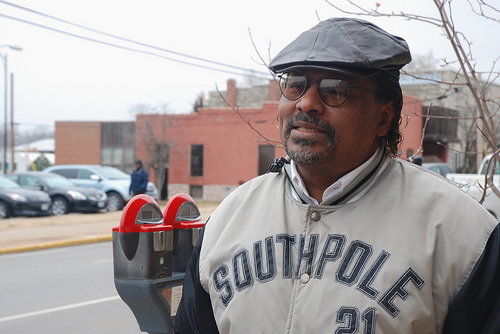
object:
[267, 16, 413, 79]
hat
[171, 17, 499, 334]
man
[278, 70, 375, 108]
glasses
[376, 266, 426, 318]
letters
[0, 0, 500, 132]
sky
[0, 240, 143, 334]
street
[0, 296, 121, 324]
line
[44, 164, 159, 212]
car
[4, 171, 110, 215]
car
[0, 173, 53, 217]
car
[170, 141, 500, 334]
jacket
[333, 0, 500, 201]
tree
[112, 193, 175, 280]
meter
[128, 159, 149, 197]
person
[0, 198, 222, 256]
sidewalk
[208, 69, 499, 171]
building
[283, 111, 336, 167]
goatee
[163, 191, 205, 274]
meters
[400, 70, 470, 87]
branch